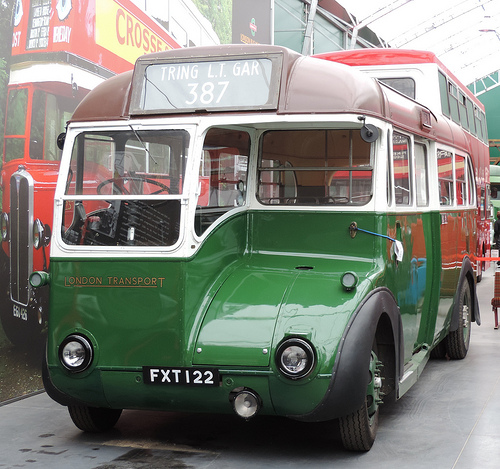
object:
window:
[411, 137, 430, 206]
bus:
[1, 0, 211, 346]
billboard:
[1, 0, 182, 77]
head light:
[272, 335, 323, 380]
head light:
[56, 333, 90, 372]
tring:
[160, 64, 200, 81]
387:
[185, 81, 230, 106]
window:
[390, 128, 414, 206]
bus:
[40, 41, 485, 456]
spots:
[28, 429, 168, 467]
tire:
[334, 342, 382, 451]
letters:
[149, 368, 216, 385]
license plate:
[142, 366, 220, 390]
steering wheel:
[94, 173, 172, 239]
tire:
[444, 278, 471, 362]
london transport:
[59, 273, 165, 290]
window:
[437, 146, 455, 207]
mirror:
[32, 218, 45, 250]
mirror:
[359, 124, 378, 143]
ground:
[0, 288, 499, 466]